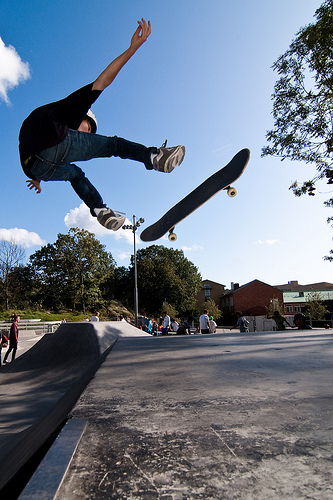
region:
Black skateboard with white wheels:
[124, 129, 267, 272]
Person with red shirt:
[0, 303, 35, 372]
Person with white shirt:
[198, 300, 214, 336]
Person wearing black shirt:
[5, 15, 197, 250]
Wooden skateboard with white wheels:
[110, 129, 274, 269]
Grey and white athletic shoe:
[137, 129, 195, 180]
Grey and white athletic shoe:
[91, 179, 139, 244]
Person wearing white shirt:
[161, 306, 172, 342]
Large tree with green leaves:
[26, 216, 118, 325]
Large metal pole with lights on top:
[122, 204, 149, 331]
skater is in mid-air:
[12, 16, 249, 243]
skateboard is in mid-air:
[131, 147, 250, 244]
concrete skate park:
[2, 317, 330, 498]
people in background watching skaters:
[0, 301, 332, 366]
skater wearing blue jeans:
[20, 129, 150, 207]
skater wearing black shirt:
[16, 78, 104, 153]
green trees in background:
[2, 234, 220, 328]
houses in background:
[197, 274, 332, 314]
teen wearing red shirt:
[4, 313, 20, 363]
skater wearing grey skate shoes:
[93, 142, 186, 230]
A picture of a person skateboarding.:
[5, 15, 305, 444]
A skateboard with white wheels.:
[140, 150, 260, 251]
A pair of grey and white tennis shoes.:
[78, 137, 195, 234]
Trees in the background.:
[14, 227, 204, 305]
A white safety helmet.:
[65, 97, 108, 137]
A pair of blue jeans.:
[12, 122, 159, 201]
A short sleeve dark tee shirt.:
[15, 76, 108, 160]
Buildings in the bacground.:
[193, 274, 327, 336]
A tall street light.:
[117, 208, 149, 330]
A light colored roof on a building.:
[281, 285, 328, 305]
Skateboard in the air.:
[139, 146, 258, 245]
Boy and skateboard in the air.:
[14, 15, 250, 243]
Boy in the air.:
[16, 14, 187, 229]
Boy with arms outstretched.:
[14, 11, 186, 232]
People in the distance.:
[142, 307, 312, 339]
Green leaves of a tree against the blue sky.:
[261, 0, 332, 270]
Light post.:
[121, 211, 145, 328]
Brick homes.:
[195, 274, 331, 324]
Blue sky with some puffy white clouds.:
[2, 0, 328, 280]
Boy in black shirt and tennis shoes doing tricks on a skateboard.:
[18, 13, 253, 243]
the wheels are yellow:
[159, 185, 247, 250]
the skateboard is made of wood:
[109, 142, 271, 249]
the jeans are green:
[42, 141, 148, 194]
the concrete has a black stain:
[96, 418, 296, 476]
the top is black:
[15, 93, 82, 151]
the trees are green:
[34, 240, 183, 299]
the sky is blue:
[95, 22, 257, 85]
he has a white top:
[195, 314, 215, 328]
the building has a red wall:
[230, 287, 290, 313]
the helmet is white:
[88, 109, 107, 127]